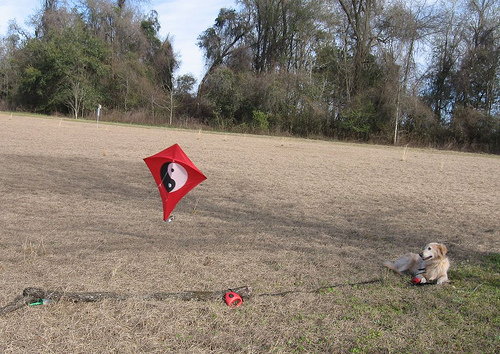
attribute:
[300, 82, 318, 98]
leaves — green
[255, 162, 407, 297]
grass —  dead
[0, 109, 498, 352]
grass —  short,  brown